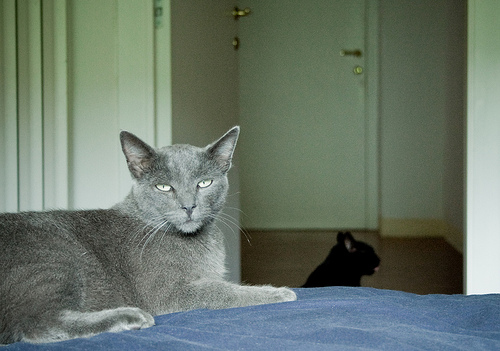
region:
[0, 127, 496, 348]
Two cats occupying bedroom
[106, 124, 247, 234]
Grey cat posing for camera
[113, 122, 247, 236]
Grey cats with perked ears and green eyes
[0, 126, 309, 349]
Grey cat lying on blue bed spread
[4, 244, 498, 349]
Made blue bedspread with cat lying on it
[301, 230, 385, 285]
Black cat facing right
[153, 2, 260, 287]
White opened bedroom door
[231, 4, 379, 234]
Closed door with bronze knob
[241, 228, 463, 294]
Black cat on wooden floor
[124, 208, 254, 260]
Flowing white cat whiskers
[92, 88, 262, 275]
the cats ears are pointy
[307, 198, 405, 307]
there is a black cat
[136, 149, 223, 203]
the cats eyes look like their glowing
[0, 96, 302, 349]
the cat is gray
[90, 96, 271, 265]
the cat has whiskers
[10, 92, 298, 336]
the cat is on the bed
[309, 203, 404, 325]
the black cat is in the floor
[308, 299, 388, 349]
the blanket is blue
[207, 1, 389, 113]
the door handle is gold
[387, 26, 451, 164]
the walls are white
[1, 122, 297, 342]
A grey cat laying down.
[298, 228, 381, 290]
A black cat on the floor.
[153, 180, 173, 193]
The eye of the cat.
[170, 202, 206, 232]
The cat's mouth.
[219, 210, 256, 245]
The cat's white whiskers.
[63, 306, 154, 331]
The cat's grey foot.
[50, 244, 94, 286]
Grey fur on the cat.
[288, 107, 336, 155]
Part of the door.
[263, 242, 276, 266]
Part of the floor.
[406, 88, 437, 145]
Part of the white wall.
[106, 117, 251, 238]
head of a cat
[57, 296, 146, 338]
leg of a cat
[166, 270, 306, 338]
leg of a cat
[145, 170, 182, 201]
eye of a cat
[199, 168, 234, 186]
eye of a cat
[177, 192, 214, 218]
nose of a cat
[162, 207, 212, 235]
mouth of a cat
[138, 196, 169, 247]
whisker of a cat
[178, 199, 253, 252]
whisker of a cat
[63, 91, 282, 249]
a head of a cat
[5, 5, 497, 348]
a scene during the day time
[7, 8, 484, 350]
a scene inside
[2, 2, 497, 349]
a scene of a bedroom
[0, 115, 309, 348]
a gray cat looking at camera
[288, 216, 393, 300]
a black cat on the ground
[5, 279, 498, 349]
a blue blanket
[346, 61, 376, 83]
a gold doorknob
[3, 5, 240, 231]
a white wall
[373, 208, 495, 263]
tan trim on the wall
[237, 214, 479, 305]
a brown floor